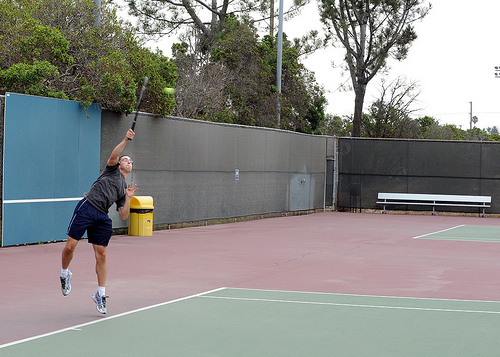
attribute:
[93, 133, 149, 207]
man — playing, plying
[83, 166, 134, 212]
tshirt — gray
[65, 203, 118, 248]
shorts — blue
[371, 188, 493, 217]
bench — white, empty, long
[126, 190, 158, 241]
trashbin — yellow